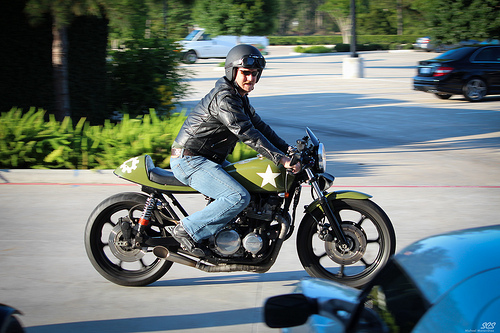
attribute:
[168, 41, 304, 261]
man — motorist, outdoors, experiencing day, riding, looking right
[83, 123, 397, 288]
motorcycle — motorbike, green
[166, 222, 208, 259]
shoe — black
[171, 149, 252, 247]
jeans — blue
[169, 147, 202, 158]
belt — brown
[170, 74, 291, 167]
jacket — black, leather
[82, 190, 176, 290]
wheel — existing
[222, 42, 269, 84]
helmet — black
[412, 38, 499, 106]
car — existing, parked, black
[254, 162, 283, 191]
logo — star, white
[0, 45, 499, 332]
parking lot — existing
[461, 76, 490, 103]
tire — black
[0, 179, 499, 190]
line — red